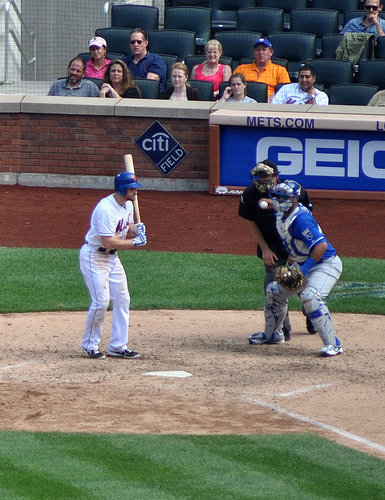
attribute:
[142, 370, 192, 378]
home plate — white 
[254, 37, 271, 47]
hat — blue 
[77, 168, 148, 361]
person — batting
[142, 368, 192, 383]
homeplate — white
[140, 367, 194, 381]
base — white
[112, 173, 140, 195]
helmet — blue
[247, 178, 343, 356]
catcher — throwing , white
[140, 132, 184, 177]
citifield — blue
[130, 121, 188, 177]
sign — blue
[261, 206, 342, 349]
uniform — blue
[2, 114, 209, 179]
brick — red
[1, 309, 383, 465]
track — dirt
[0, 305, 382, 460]
dirt — light, brown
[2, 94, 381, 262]
wall — brick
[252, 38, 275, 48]
cap — blue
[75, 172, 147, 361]
man — baseball player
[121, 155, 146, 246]
bat — wooden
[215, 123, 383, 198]
sign — blue, white, geico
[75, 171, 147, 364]
player — baseball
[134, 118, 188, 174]
sign — citifield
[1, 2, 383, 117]
netting — protective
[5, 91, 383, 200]
wall — brick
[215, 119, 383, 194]
advertisement — blue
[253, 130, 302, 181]
letters — white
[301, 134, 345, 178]
letters — white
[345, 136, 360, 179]
letters — white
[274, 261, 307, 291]
mitt — baseball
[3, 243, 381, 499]
field — green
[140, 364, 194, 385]
homebase — empty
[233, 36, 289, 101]
man — sitting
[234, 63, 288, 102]
shirt — orange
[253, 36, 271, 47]
cap — blue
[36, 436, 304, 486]
grass — light green, mowed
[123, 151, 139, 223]
baseball bat — tan colored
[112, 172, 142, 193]
helmet — blue, red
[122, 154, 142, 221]
baseball bat — wooden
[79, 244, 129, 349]
pants — white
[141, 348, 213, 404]
home base — white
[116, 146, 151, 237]
baseball bat — wooden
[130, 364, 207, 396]
homeplate — white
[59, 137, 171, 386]
man — batting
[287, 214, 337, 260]
jersey — blue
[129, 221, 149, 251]
gloves — blue, white